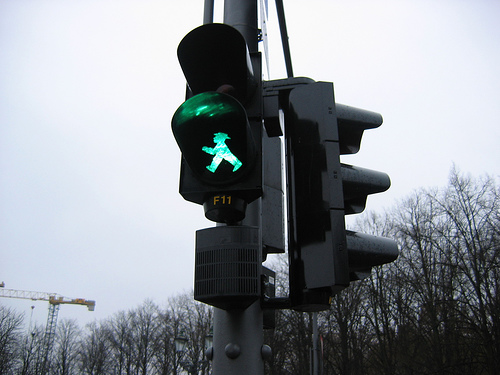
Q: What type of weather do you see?
A: It is overcast.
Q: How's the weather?
A: It is overcast.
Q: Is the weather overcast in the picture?
A: Yes, it is overcast.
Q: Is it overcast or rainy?
A: It is overcast.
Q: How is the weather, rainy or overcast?
A: It is overcast.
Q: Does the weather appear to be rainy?
A: No, it is overcast.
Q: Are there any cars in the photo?
A: No, there are no cars.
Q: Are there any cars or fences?
A: No, there are no cars or fences.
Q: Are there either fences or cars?
A: No, there are no cars or fences.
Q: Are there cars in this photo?
A: No, there are no cars.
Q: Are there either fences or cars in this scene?
A: No, there are no cars or fences.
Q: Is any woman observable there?
A: No, there are no women.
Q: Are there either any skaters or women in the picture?
A: No, there are no women or skaters.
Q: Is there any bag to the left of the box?
A: No, there is a man to the left of the box.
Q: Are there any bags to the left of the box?
A: No, there is a man to the left of the box.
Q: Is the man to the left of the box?
A: Yes, the man is to the left of the box.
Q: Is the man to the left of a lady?
A: No, the man is to the left of the box.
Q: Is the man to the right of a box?
A: No, the man is to the left of a box.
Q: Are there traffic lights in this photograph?
A: Yes, there is a traffic light.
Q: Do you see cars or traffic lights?
A: Yes, there is a traffic light.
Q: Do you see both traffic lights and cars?
A: No, there is a traffic light but no cars.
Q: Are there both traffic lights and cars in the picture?
A: No, there is a traffic light but no cars.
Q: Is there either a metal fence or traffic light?
A: Yes, there is a metal traffic light.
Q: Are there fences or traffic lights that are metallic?
A: Yes, the traffic light is metallic.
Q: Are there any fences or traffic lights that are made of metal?
A: Yes, the traffic light is made of metal.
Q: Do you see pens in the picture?
A: No, there are no pens.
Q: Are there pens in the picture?
A: No, there are no pens.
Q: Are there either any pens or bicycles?
A: No, there are no pens or bicycles.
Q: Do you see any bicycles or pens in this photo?
A: No, there are no pens or bicycles.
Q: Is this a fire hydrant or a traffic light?
A: This is a traffic light.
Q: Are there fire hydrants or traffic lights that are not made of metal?
A: No, there is a traffic light but it is made of metal.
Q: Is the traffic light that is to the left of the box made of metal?
A: Yes, the traffic light is made of metal.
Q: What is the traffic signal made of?
A: The traffic signal is made of metal.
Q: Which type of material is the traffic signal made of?
A: The traffic signal is made of metal.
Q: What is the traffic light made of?
A: The traffic signal is made of metal.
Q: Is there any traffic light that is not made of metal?
A: No, there is a traffic light but it is made of metal.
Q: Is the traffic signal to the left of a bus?
A: No, the traffic signal is to the left of the box.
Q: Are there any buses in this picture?
A: No, there are no buses.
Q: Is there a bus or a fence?
A: No, there are no buses or fences.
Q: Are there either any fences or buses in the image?
A: No, there are no buses or fences.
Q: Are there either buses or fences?
A: No, there are no buses or fences.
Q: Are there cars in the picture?
A: No, there are no cars.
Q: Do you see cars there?
A: No, there are no cars.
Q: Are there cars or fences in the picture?
A: No, there are no cars or fences.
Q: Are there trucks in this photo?
A: No, there are no trucks.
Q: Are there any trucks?
A: No, there are no trucks.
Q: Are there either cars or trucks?
A: No, there are no trucks or cars.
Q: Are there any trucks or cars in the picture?
A: No, there are no trucks or cars.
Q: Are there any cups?
A: No, there are no cups.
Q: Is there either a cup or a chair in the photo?
A: No, there are no cups or chairs.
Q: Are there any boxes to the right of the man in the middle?
A: Yes, there is a box to the right of the man.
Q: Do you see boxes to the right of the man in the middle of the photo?
A: Yes, there is a box to the right of the man.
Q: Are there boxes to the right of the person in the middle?
A: Yes, there is a box to the right of the man.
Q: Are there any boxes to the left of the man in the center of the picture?
A: No, the box is to the right of the man.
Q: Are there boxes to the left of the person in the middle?
A: No, the box is to the right of the man.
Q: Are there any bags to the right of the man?
A: No, there is a box to the right of the man.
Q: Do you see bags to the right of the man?
A: No, there is a box to the right of the man.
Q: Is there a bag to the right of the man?
A: No, there is a box to the right of the man.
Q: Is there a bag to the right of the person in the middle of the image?
A: No, there is a box to the right of the man.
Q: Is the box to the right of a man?
A: Yes, the box is to the right of a man.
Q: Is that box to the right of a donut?
A: No, the box is to the right of a man.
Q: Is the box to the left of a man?
A: No, the box is to the right of a man.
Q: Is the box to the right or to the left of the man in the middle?
A: The box is to the right of the man.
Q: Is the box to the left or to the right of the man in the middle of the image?
A: The box is to the right of the man.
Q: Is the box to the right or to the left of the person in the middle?
A: The box is to the right of the man.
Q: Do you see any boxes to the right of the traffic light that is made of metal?
A: Yes, there is a box to the right of the traffic light.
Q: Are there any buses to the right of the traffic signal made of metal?
A: No, there is a box to the right of the traffic signal.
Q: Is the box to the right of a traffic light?
A: Yes, the box is to the right of a traffic light.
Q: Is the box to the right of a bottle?
A: No, the box is to the right of a traffic light.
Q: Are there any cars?
A: No, there are no cars.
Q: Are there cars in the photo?
A: No, there are no cars.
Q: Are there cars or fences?
A: No, there are no cars or fences.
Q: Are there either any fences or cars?
A: No, there are no cars or fences.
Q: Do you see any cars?
A: No, there are no cars.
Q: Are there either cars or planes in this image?
A: No, there are no cars or planes.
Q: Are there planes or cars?
A: No, there are no cars or planes.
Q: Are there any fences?
A: No, there are no fences.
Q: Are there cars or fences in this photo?
A: No, there are no fences or cars.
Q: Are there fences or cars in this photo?
A: No, there are no fences or cars.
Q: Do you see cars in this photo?
A: No, there are no cars.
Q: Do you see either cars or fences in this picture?
A: No, there are no cars or fences.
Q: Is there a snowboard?
A: No, there are no snowboards.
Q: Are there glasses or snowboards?
A: No, there are no snowboards or glasses.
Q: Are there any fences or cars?
A: No, there are no cars or fences.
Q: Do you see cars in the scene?
A: No, there are no cars.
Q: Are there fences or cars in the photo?
A: No, there are no cars or fences.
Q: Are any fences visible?
A: No, there are no fences.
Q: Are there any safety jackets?
A: No, there are no safety jackets.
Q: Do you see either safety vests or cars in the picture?
A: No, there are no safety vests or cars.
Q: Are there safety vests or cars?
A: No, there are no safety vests or cars.